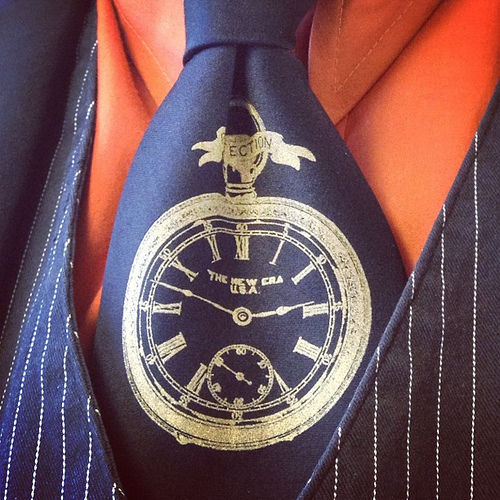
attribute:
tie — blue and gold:
[93, 7, 407, 494]